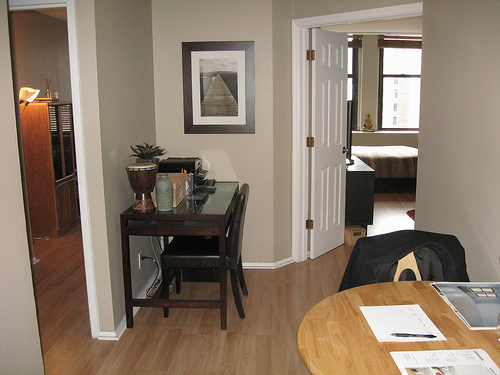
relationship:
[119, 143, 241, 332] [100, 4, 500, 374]
desk in room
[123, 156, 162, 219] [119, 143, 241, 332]
bongo drum on desk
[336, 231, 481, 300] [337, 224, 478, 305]
jacket on a chair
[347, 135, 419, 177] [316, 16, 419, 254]
bed in bedroom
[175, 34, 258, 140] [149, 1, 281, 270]
picture on wall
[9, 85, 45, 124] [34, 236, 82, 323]
lamp on floor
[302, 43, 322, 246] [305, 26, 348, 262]
hinges are on door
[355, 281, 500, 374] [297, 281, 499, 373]
papers are on table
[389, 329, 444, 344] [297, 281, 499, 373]
pen on table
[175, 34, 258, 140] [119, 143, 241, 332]
picture above desk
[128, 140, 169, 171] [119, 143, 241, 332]
plant on desk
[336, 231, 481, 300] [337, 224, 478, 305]
jacket on chair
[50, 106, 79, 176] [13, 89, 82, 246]
reflection on cabinet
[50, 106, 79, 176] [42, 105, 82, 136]
reflection of a window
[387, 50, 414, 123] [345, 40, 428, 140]
sunlight in window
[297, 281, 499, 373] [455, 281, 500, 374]
table in corner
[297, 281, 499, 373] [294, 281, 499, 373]
table made of table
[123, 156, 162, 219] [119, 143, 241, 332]
bongo drum on a desk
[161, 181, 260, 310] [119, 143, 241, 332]
chair in front of desk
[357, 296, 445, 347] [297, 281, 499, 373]
paper on table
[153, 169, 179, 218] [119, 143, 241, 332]
vase on desk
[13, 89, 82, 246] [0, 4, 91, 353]
cabinet in hallway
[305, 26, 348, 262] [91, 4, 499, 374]
door between rooms